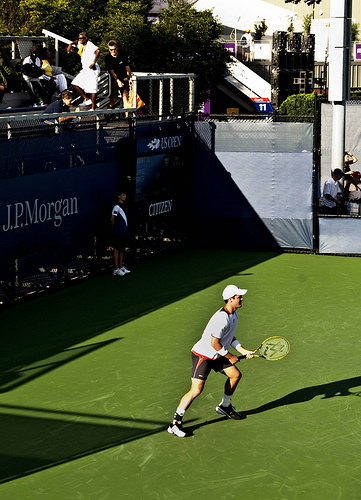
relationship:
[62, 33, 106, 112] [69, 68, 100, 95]
man wearing shorts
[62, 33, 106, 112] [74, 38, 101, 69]
man wearing shirt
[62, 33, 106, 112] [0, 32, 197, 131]
man in stands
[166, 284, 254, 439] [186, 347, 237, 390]
guy wearing pair of shorts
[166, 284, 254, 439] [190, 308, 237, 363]
guy in shirt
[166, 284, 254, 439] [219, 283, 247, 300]
guy in cap